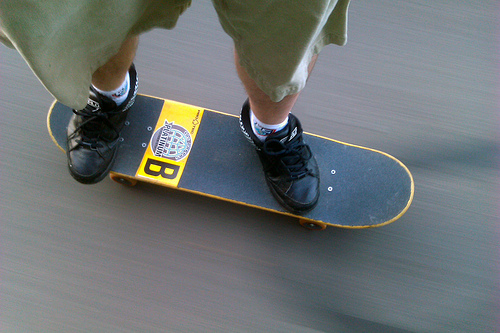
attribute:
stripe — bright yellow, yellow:
[133, 96, 201, 188]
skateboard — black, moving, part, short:
[46, 86, 415, 237]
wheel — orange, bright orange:
[105, 168, 140, 190]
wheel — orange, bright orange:
[295, 215, 330, 235]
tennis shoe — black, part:
[237, 96, 329, 215]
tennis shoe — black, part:
[63, 60, 141, 185]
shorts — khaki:
[0, 1, 354, 114]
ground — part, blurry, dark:
[0, 1, 498, 327]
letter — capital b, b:
[143, 156, 181, 182]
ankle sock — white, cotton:
[247, 110, 292, 145]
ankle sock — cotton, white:
[91, 71, 136, 111]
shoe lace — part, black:
[262, 122, 314, 187]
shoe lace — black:
[71, 105, 120, 153]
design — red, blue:
[252, 121, 275, 141]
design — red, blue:
[109, 80, 131, 101]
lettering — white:
[278, 127, 300, 145]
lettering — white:
[83, 96, 100, 111]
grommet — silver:
[329, 166, 338, 178]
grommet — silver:
[326, 183, 334, 193]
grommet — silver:
[148, 126, 154, 131]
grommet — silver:
[141, 140, 148, 150]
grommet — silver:
[125, 121, 131, 126]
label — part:
[148, 117, 194, 163]